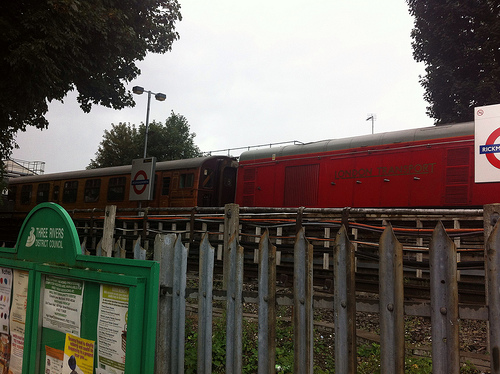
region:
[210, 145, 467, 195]
red train on the bridge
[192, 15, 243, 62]
white clouds in blue sky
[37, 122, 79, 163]
white clouds in blue sky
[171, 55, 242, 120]
white clouds in blue sky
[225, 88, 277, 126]
white clouds in blue sky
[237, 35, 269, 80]
white clouds in blue sky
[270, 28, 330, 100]
white clouds in blue sky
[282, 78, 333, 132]
white clouds in blue sky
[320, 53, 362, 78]
white clouds in blue sky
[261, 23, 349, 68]
white clouds in blue sky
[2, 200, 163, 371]
Green wood sign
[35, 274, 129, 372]
Papers hanging under glass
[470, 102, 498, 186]
White sign with a red circle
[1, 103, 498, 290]
Two car train on a train track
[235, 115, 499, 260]
red car of a train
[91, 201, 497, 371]
Rusted metal fence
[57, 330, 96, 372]
White and yellow flyer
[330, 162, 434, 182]
Gold lettering on red paint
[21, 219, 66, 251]
White lettering on a green frame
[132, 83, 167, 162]
Two light street lamp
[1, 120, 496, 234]
train with red cars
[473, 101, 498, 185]
red, white and blue sign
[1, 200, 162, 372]
green board with public notices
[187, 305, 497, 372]
grass near the train tracks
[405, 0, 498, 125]
green, leafy tree behind the tracks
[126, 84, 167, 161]
street lamp in front of a tree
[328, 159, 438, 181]
LONDON TRANSPORT on side of train car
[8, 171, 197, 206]
windows on a train car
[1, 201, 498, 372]
picket fene near the railroad tracks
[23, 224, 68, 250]
sign reads THREE RIVERS DISTRICT COUNCIL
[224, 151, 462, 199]
red train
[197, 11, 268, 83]
white clouds in blue sky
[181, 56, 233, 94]
white clouds in blue sky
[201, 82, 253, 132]
white clouds in blue sky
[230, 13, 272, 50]
white clouds in blue sky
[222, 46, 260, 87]
white clouds in blue sky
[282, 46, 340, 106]
white clouds in blue sky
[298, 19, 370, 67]
white clouds in blue sky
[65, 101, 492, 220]
This is in london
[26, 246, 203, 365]
This is a green board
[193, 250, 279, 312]
This is a fence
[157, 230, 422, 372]
The fence is wooden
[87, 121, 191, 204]
This is a sign for the train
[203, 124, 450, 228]
The train is red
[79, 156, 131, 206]
These are windows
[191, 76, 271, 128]
There is no sun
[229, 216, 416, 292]
The tracks are rusted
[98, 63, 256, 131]
These are lights